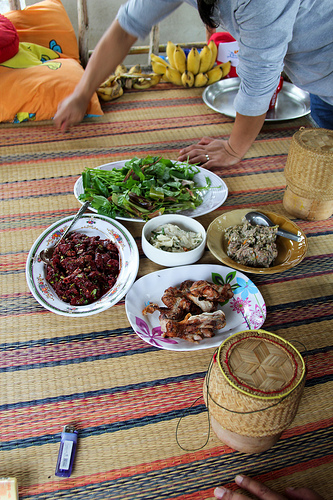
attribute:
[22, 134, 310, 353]
food — untouched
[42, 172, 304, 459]
food — red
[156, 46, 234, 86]
bananas — yellow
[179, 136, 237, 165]
hand — of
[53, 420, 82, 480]
lighter — blue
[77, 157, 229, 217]
plate — large, oval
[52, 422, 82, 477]
lighter — blue 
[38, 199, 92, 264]
spoon — silver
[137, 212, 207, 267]
bowl — white, round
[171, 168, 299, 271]
bowl — round, brown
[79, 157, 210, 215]
salad — green, mix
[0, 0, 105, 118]
pillow — orange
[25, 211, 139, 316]
plate — white